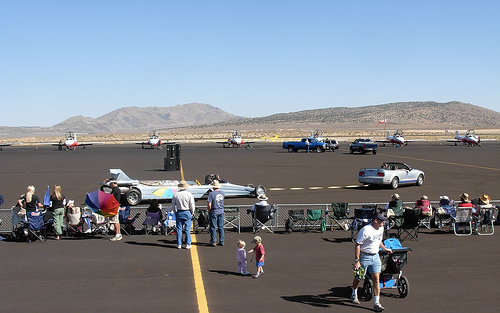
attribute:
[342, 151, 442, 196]
convertible — silver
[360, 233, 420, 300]
stroller — blue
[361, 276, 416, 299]
wheels — black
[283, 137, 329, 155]
pickup truck — blue, large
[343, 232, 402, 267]
shirt — white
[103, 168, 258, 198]
car — jet racer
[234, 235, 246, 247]
hair — blonde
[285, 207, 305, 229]
lawn chair — black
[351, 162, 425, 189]
mustang — silver, GT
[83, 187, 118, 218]
umbrella — multi-colored, large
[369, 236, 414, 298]
stroller — black, blue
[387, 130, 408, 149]
airplane — red, white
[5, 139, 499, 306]
track — paved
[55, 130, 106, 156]
plane — red, white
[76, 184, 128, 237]
umbrella — colorful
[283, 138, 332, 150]
truck — blue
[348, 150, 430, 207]
convertible — silver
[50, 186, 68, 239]
woman — blonde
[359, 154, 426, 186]
mercedes benz — silver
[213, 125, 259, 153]
airplane — white, red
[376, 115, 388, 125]
flag — red, white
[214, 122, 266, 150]
plane — red, white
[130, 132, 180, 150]
airplane — white, red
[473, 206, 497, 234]
chair — lounge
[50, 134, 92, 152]
airplane — red, white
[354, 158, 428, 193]
car — sports car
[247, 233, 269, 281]
child — small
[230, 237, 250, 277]
child — small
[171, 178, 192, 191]
hat — white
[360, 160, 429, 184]
mustang — ford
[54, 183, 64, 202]
hair — long